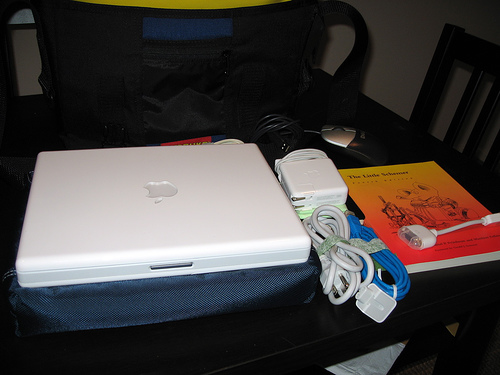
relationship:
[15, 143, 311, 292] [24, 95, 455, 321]
computer on desktop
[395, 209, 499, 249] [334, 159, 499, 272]
cord on top of book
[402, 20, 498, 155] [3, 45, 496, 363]
chair tucked into desk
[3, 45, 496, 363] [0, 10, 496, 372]
desk in room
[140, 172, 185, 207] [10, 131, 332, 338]
logo on laptop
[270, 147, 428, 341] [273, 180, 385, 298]
plug-in for charger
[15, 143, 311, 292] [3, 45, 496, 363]
computer on desk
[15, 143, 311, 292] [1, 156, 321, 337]
computer sitting on blue bag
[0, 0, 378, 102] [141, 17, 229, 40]
chair has stripe